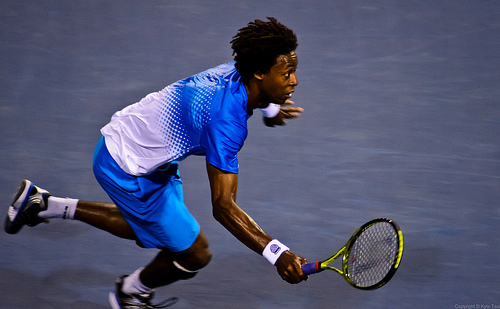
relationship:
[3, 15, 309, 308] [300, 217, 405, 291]
man swinging racket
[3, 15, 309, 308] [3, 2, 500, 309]
man across tennis court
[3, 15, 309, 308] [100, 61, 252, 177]
man has shirt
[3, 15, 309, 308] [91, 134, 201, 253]
man wearing shorts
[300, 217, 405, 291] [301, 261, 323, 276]
racket has handle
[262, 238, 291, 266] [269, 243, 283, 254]
wristband has symbol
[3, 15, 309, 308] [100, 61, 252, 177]
man wearing shirt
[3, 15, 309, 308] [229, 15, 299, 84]
man has hair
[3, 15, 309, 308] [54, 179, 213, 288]
man has legs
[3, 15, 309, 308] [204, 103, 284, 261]
man has arms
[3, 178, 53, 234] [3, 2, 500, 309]
foot off tennis court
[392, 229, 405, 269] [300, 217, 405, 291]
line on top of racket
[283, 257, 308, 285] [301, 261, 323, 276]
fingers around handle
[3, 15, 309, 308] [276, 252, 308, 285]
man has hand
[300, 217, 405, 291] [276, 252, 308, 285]
racket in hand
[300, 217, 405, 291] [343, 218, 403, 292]
racket has head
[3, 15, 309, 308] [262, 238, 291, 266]
man wearing wristband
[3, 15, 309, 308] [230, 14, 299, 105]
man has head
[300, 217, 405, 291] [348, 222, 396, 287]
racket has strings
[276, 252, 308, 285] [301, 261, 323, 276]
hand gripping handle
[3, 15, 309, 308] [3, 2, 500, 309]
man on tennis court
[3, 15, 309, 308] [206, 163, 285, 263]
man has arm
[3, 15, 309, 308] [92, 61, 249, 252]
man wearing outfit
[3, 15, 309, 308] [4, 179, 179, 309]
man wearing shoes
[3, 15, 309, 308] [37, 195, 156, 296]
man wearing socks